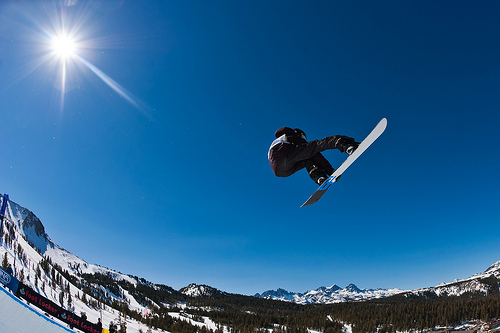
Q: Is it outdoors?
A: Yes, it is outdoors.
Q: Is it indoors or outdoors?
A: It is outdoors.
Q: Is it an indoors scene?
A: No, it is outdoors.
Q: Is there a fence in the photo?
A: No, there are no fences.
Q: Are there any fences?
A: No, there are no fences.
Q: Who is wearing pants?
A: The man is wearing pants.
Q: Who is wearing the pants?
A: The man is wearing pants.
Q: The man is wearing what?
A: The man is wearing pants.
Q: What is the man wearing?
A: The man is wearing pants.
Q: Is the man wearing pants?
A: Yes, the man is wearing pants.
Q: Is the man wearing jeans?
A: No, the man is wearing pants.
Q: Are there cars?
A: No, there are no cars.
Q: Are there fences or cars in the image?
A: No, there are no cars or fences.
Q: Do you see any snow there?
A: Yes, there is snow.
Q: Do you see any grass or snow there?
A: Yes, there is snow.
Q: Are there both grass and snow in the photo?
A: No, there is snow but no grass.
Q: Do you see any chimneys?
A: No, there are no chimneys.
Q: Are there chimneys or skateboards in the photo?
A: No, there are no chimneys or skateboards.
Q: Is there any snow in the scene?
A: Yes, there is snow.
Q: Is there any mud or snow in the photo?
A: Yes, there is snow.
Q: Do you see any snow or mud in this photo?
A: Yes, there is snow.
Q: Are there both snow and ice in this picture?
A: No, there is snow but no ice.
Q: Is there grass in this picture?
A: No, there is no grass.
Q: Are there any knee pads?
A: No, there are no knee pads.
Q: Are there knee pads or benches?
A: No, there are no knee pads or benches.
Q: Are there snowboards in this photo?
A: Yes, there is a snowboard.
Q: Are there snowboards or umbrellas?
A: Yes, there is a snowboard.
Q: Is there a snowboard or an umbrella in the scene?
A: Yes, there is a snowboard.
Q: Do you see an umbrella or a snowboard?
A: Yes, there is a snowboard.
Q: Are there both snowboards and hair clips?
A: No, there is a snowboard but no hair clips.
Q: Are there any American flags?
A: No, there are no American flags.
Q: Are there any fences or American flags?
A: No, there are no American flags or fences.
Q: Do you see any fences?
A: No, there are no fences.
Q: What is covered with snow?
A: The hill is covered with snow.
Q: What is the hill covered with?
A: The hill is covered with snow.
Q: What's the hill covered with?
A: The hill is covered with snow.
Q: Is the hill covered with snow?
A: Yes, the hill is covered with snow.